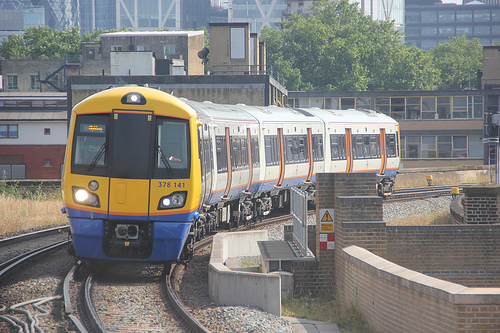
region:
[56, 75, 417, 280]
passenger train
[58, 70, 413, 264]
passenger train with 4 cars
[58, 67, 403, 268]
passenger train with yellow and blue front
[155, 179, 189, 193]
numbers on passenger train noting which train it is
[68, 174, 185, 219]
headlights of passenger train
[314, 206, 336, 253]
warning signs on a brick wall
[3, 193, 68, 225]
patchy area of brown grass to the left of the passenger train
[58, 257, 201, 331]
curve of the railroad track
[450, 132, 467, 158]
window of building behind railroad track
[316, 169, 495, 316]
brick wall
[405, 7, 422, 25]
a window on a building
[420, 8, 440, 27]
a window on a building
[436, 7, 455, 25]
a window on a building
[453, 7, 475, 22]
a window on a building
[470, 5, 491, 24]
a window on a building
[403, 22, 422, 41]
a window on a building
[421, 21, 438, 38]
a window on a building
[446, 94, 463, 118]
a window on a building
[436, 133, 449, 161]
a window on a building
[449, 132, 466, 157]
a window on a building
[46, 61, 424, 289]
a train turning a corner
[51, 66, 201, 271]
the train's face is yellow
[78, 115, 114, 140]
small digital display in the window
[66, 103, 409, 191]
many windows on a train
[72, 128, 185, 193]
two black windshield wipers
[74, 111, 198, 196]
the front windows have windshield wipers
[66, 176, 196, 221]
headlights on a train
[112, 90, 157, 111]
light on top of a train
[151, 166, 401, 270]
wheels on a train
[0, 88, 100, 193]
a building with red paint on the bottom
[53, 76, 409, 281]
Train on rails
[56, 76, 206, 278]
Front of train is yellow and blue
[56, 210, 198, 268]
Bumper of train is blue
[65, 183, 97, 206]
Highlights are turn on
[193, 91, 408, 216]
Car of train is white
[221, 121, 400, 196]
Doors of train are orange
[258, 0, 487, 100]
Trees behind building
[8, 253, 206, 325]
Rails of train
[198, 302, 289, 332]
Gravel on side of rail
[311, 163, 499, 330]
Wall of brick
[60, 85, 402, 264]
yellow and blue train is moving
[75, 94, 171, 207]
train has three headlights that are on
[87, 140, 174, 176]
wind-shield wipers on front of train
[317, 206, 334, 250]
warning signs near train tracks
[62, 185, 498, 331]
train tracks under train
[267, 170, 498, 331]
brick walls next to train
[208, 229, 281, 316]
white wall right next to train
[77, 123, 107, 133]
sign on front of train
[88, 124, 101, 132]
orange lettering on sign on front of train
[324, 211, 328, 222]
exclamation point on warning sign